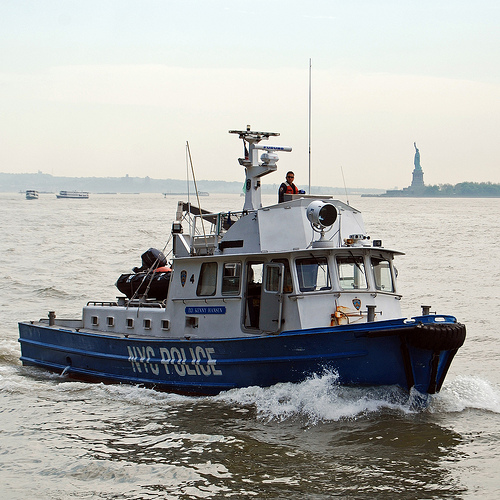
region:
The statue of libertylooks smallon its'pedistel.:
[408, 142, 425, 197]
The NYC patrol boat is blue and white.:
[18, 57, 466, 408]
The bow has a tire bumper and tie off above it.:
[408, 305, 467, 397]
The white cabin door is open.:
[234, 261, 284, 334]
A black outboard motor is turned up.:
[133, 247, 167, 271]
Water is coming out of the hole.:
[57, 356, 74, 376]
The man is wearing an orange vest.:
[282, 172, 300, 194]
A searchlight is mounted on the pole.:
[306, 200, 338, 242]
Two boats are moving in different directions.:
[23, 188, 96, 200]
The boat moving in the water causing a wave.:
[221, 365, 471, 425]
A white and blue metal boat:
[18, 116, 468, 397]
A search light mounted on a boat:
[308, 199, 336, 249]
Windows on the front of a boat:
[295, 254, 395, 291]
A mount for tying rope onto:
[364, 302, 377, 321]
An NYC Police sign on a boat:
[124, 346, 226, 377]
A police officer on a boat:
[275, 169, 306, 205]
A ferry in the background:
[53, 189, 93, 200]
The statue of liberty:
[404, 139, 429, 190]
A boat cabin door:
[259, 260, 283, 332]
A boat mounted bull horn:
[347, 232, 372, 245]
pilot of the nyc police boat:
[279, 170, 305, 203]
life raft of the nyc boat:
[114, 247, 176, 298]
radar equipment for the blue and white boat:
[250, 143, 292, 152]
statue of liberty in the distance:
[410, 143, 423, 194]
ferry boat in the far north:
[56, 189, 90, 200]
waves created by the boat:
[225, 380, 394, 415]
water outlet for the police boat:
[59, 359, 74, 370]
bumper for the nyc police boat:
[407, 320, 469, 343]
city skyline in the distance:
[78, 174, 163, 179]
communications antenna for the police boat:
[304, 58, 314, 198]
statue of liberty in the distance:
[402, 139, 432, 198]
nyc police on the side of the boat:
[118, 336, 228, 393]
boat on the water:
[9, 114, 471, 407]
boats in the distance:
[24, 188, 94, 203]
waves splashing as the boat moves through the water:
[221, 369, 498, 441]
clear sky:
[4, 6, 232, 171]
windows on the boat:
[196, 247, 404, 314]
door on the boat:
[234, 257, 286, 337]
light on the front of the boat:
[304, 194, 338, 251]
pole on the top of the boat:
[286, 51, 336, 208]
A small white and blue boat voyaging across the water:
[11, 112, 473, 416]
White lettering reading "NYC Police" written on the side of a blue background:
[91, 340, 228, 382]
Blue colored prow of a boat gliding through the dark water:
[365, 285, 470, 420]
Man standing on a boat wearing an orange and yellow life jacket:
[271, 163, 316, 220]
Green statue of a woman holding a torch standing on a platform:
[402, 134, 432, 190]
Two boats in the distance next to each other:
[16, 180, 111, 204]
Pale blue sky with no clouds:
[71, 15, 416, 122]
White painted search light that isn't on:
[301, 176, 353, 258]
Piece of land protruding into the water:
[381, 177, 499, 212]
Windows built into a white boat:
[203, 255, 410, 305]